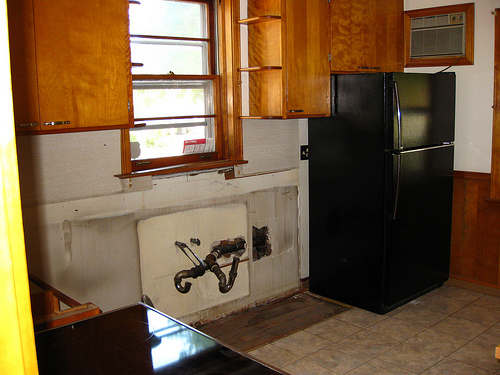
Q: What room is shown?
A: It is a kitchen.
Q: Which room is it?
A: It is a kitchen.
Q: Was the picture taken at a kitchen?
A: Yes, it was taken in a kitchen.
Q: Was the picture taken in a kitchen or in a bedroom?
A: It was taken at a kitchen.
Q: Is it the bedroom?
A: No, it is the kitchen.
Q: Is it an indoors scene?
A: Yes, it is indoors.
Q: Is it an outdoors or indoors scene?
A: It is indoors.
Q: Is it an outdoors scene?
A: No, it is indoors.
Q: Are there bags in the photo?
A: No, there are no bags.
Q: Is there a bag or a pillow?
A: No, there are no bags or pillows.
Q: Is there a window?
A: Yes, there is a window.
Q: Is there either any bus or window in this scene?
A: Yes, there is a window.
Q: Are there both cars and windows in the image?
A: No, there is a window but no cars.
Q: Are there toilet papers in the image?
A: No, there are no toilet papers.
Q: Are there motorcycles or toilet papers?
A: No, there are no toilet papers or motorcycles.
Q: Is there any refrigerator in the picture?
A: Yes, there is a refrigerator.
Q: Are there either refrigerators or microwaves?
A: Yes, there is a refrigerator.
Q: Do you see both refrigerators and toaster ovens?
A: No, there is a refrigerator but no toaster ovens.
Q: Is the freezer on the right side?
A: Yes, the freezer is on the right of the image.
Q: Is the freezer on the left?
A: No, the freezer is on the right of the image.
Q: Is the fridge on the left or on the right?
A: The fridge is on the right of the image.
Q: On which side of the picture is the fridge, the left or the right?
A: The fridge is on the right of the image.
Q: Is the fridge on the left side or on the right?
A: The fridge is on the right of the image.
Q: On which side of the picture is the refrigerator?
A: The refrigerator is on the right of the image.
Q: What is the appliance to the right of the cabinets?
A: The appliance is a refrigerator.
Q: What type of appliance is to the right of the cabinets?
A: The appliance is a refrigerator.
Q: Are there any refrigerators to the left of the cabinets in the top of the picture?
A: No, the refrigerator is to the right of the cabinets.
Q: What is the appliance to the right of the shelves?
A: The appliance is a refrigerator.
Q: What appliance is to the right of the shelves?
A: The appliance is a refrigerator.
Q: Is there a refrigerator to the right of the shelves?
A: Yes, there is a refrigerator to the right of the shelves.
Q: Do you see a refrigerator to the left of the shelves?
A: No, the refrigerator is to the right of the shelves.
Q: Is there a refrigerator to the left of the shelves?
A: No, the refrigerator is to the right of the shelves.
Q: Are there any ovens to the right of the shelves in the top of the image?
A: No, there is a refrigerator to the right of the shelves.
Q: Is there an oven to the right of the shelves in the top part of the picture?
A: No, there is a refrigerator to the right of the shelves.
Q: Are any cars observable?
A: No, there are no cars.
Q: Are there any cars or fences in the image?
A: No, there are no cars or fences.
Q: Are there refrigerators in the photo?
A: Yes, there is a refrigerator.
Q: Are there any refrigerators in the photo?
A: Yes, there is a refrigerator.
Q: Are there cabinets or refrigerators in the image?
A: Yes, there is a refrigerator.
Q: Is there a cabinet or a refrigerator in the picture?
A: Yes, there is a refrigerator.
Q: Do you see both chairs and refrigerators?
A: No, there is a refrigerator but no chairs.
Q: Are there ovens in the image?
A: No, there are no ovens.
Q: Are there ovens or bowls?
A: No, there are no ovens or bowls.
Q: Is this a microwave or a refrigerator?
A: This is a refrigerator.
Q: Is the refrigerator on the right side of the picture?
A: Yes, the refrigerator is on the right of the image.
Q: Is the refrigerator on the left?
A: No, the refrigerator is on the right of the image.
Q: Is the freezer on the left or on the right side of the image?
A: The freezer is on the right of the image.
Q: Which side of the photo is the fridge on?
A: The fridge is on the right of the image.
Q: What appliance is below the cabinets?
A: The appliance is a refrigerator.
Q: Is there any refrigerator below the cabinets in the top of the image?
A: Yes, there is a refrigerator below the cabinets.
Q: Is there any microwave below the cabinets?
A: No, there is a refrigerator below the cabinets.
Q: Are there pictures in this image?
A: No, there are no pictures.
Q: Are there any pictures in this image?
A: No, there are no pictures.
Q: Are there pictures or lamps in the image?
A: No, there are no pictures or lamps.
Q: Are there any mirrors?
A: No, there are no mirrors.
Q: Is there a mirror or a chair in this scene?
A: No, there are no mirrors or chairs.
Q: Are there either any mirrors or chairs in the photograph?
A: No, there are no mirrors or chairs.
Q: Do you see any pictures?
A: No, there are no pictures.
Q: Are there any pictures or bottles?
A: No, there are no pictures or bottles.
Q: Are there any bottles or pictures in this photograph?
A: No, there are no pictures or bottles.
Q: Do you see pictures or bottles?
A: No, there are no pictures or bottles.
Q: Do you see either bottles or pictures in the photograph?
A: No, there are no pictures or bottles.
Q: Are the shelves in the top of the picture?
A: Yes, the shelves are in the top of the image.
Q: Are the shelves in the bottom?
A: No, the shelves are in the top of the image.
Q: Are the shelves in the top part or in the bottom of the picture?
A: The shelves are in the top of the image.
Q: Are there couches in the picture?
A: No, there are no couches.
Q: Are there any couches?
A: No, there are no couches.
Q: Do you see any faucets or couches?
A: No, there are no couches or faucets.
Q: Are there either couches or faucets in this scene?
A: No, there are no couches or faucets.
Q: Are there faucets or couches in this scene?
A: No, there are no couches or faucets.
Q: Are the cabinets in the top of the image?
A: Yes, the cabinets are in the top of the image.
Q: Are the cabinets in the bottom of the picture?
A: No, the cabinets are in the top of the image.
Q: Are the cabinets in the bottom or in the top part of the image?
A: The cabinets are in the top of the image.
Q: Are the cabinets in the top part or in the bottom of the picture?
A: The cabinets are in the top of the image.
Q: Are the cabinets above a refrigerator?
A: Yes, the cabinets are above a refrigerator.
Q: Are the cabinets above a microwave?
A: No, the cabinets are above a refrigerator.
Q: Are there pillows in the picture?
A: No, there are no pillows.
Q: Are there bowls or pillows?
A: No, there are no pillows or bowls.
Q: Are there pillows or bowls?
A: No, there are no pillows or bowls.